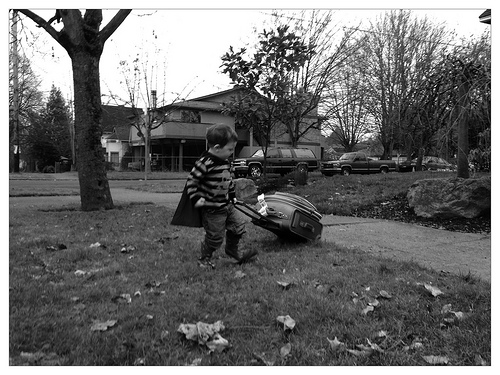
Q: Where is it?
A: This is at the yard.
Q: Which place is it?
A: It is a yard.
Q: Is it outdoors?
A: Yes, it is outdoors.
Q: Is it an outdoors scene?
A: Yes, it is outdoors.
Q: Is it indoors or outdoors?
A: It is outdoors.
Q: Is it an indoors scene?
A: No, it is outdoors.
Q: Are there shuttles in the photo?
A: No, there are no shuttles.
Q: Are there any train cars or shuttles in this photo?
A: No, there are no shuttles or train cars.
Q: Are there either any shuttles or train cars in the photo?
A: No, there are no shuttles or train cars.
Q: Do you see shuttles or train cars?
A: No, there are no shuttles or train cars.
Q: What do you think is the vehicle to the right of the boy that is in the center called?
A: The vehicle is a wagon.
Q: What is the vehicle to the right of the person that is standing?
A: The vehicle is a wagon.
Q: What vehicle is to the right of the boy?
A: The vehicle is a wagon.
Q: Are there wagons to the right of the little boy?
A: Yes, there is a wagon to the right of the boy.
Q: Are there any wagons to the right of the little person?
A: Yes, there is a wagon to the right of the boy.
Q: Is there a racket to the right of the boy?
A: No, there is a wagon to the right of the boy.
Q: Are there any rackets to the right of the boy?
A: No, there is a wagon to the right of the boy.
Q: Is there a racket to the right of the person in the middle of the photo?
A: No, there is a wagon to the right of the boy.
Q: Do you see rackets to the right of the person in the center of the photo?
A: No, there is a wagon to the right of the boy.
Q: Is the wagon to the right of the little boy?
A: Yes, the wagon is to the right of the boy.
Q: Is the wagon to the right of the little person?
A: Yes, the wagon is to the right of the boy.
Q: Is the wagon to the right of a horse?
A: No, the wagon is to the right of the boy.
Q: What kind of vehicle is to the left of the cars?
A: The vehicle is a wagon.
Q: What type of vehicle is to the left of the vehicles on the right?
A: The vehicle is a wagon.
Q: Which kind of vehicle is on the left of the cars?
A: The vehicle is a wagon.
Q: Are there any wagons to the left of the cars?
A: Yes, there is a wagon to the left of the cars.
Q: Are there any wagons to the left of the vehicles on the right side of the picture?
A: Yes, there is a wagon to the left of the cars.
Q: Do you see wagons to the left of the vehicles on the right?
A: Yes, there is a wagon to the left of the cars.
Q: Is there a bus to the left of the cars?
A: No, there is a wagon to the left of the cars.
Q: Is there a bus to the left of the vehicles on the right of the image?
A: No, there is a wagon to the left of the cars.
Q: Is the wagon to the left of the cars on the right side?
A: Yes, the wagon is to the left of the cars.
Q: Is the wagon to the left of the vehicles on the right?
A: Yes, the wagon is to the left of the cars.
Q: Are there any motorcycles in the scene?
A: No, there are no motorcycles.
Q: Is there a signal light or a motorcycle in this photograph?
A: No, there are no motorcycles or traffic lights.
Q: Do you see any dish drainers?
A: No, there are no dish drainers.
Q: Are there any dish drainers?
A: No, there are no dish drainers.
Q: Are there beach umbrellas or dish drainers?
A: No, there are no dish drainers or beach umbrellas.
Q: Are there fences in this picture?
A: No, there are no fences.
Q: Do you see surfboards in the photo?
A: No, there are no surfboards.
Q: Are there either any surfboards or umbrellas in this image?
A: No, there are no surfboards or umbrellas.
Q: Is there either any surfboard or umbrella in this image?
A: No, there are no surfboards or umbrellas.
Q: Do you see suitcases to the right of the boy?
A: Yes, there is a suitcase to the right of the boy.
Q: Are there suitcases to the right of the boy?
A: Yes, there is a suitcase to the right of the boy.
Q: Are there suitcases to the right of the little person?
A: Yes, there is a suitcase to the right of the boy.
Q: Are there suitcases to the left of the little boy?
A: No, the suitcase is to the right of the boy.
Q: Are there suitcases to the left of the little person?
A: No, the suitcase is to the right of the boy.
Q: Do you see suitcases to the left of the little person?
A: No, the suitcase is to the right of the boy.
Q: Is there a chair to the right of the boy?
A: No, there is a suitcase to the right of the boy.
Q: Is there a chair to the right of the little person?
A: No, there is a suitcase to the right of the boy.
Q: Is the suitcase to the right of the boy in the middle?
A: Yes, the suitcase is to the right of the boy.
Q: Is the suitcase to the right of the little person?
A: Yes, the suitcase is to the right of the boy.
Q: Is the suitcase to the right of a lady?
A: No, the suitcase is to the right of the boy.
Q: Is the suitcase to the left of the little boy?
A: No, the suitcase is to the right of the boy.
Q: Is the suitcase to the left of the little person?
A: No, the suitcase is to the right of the boy.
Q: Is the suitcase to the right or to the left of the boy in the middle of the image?
A: The suitcase is to the right of the boy.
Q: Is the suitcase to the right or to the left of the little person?
A: The suitcase is to the right of the boy.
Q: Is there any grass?
A: Yes, there is grass.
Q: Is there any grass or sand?
A: Yes, there is grass.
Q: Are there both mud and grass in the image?
A: No, there is grass but no mud.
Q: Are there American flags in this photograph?
A: No, there are no American flags.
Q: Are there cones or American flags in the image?
A: No, there are no American flags or cones.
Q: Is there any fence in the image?
A: No, there are no fences.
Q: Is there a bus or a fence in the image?
A: No, there are no fences or buses.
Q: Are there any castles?
A: No, there are no castles.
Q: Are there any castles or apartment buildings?
A: No, there are no castles or apartment buildings.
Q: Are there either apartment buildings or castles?
A: No, there are no castles or apartment buildings.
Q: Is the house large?
A: Yes, the house is large.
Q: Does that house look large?
A: Yes, the house is large.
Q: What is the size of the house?
A: The house is large.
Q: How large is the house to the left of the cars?
A: The house is large.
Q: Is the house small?
A: No, the house is large.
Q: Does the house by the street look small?
A: No, the house is large.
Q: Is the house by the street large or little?
A: The house is large.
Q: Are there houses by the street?
A: Yes, there is a house by the street.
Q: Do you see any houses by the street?
A: Yes, there is a house by the street.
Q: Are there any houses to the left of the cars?
A: Yes, there is a house to the left of the cars.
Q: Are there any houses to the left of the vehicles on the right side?
A: Yes, there is a house to the left of the cars.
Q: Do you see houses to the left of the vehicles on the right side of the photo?
A: Yes, there is a house to the left of the cars.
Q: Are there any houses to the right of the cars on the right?
A: No, the house is to the left of the cars.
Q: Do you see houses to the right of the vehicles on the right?
A: No, the house is to the left of the cars.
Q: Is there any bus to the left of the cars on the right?
A: No, there is a house to the left of the cars.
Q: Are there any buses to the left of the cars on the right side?
A: No, there is a house to the left of the cars.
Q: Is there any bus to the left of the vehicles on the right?
A: No, there is a house to the left of the cars.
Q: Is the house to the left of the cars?
A: Yes, the house is to the left of the cars.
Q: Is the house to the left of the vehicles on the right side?
A: Yes, the house is to the left of the cars.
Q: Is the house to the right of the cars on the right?
A: No, the house is to the left of the cars.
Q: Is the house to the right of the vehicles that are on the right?
A: No, the house is to the left of the cars.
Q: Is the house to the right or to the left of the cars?
A: The house is to the left of the cars.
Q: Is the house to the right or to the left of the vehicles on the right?
A: The house is to the left of the cars.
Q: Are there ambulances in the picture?
A: No, there are no ambulances.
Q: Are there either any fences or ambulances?
A: No, there are no ambulances or fences.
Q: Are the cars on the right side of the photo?
A: Yes, the cars are on the right of the image.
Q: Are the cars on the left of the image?
A: No, the cars are on the right of the image.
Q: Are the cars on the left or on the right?
A: The cars are on the right of the image.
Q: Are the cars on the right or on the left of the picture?
A: The cars are on the right of the image.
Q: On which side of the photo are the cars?
A: The cars are on the right of the image.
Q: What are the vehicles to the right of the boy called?
A: The vehicles are cars.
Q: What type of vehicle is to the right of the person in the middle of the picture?
A: The vehicles are cars.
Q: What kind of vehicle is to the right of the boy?
A: The vehicles are cars.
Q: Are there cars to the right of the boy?
A: Yes, there are cars to the right of the boy.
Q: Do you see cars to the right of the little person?
A: Yes, there are cars to the right of the boy.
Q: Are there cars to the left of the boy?
A: No, the cars are to the right of the boy.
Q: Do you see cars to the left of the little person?
A: No, the cars are to the right of the boy.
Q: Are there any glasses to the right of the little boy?
A: No, there are cars to the right of the boy.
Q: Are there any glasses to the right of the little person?
A: No, there are cars to the right of the boy.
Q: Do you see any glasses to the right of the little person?
A: No, there are cars to the right of the boy.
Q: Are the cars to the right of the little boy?
A: Yes, the cars are to the right of the boy.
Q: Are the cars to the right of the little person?
A: Yes, the cars are to the right of the boy.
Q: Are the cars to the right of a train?
A: No, the cars are to the right of the boy.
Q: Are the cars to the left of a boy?
A: No, the cars are to the right of a boy.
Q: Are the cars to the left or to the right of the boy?
A: The cars are to the right of the boy.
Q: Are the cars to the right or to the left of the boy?
A: The cars are to the right of the boy.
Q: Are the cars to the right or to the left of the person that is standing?
A: The cars are to the right of the boy.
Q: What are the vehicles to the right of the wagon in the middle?
A: The vehicles are cars.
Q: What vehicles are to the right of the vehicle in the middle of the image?
A: The vehicles are cars.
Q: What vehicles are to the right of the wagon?
A: The vehicles are cars.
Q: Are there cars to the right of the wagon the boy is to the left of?
A: Yes, there are cars to the right of the wagon.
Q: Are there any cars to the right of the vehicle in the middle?
A: Yes, there are cars to the right of the wagon.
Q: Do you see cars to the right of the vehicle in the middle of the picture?
A: Yes, there are cars to the right of the wagon.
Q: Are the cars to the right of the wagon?
A: Yes, the cars are to the right of the wagon.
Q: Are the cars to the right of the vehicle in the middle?
A: Yes, the cars are to the right of the wagon.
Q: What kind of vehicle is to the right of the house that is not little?
A: The vehicles are cars.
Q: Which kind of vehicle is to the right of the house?
A: The vehicles are cars.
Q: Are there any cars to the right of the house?
A: Yes, there are cars to the right of the house.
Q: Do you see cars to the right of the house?
A: Yes, there are cars to the right of the house.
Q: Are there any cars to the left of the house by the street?
A: No, the cars are to the right of the house.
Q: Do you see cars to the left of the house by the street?
A: No, the cars are to the right of the house.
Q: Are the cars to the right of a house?
A: Yes, the cars are to the right of a house.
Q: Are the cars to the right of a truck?
A: No, the cars are to the right of a house.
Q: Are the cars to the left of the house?
A: No, the cars are to the right of the house.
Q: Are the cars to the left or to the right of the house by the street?
A: The cars are to the right of the house.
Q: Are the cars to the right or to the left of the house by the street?
A: The cars are to the right of the house.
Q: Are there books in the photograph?
A: No, there are no books.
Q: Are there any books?
A: No, there are no books.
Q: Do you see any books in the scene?
A: No, there are no books.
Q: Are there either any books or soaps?
A: No, there are no books or soaps.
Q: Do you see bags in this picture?
A: Yes, there is a bag.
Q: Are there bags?
A: Yes, there is a bag.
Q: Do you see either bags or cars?
A: Yes, there is a bag.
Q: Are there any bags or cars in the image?
A: Yes, there is a bag.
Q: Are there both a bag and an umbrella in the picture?
A: No, there is a bag but no umbrellas.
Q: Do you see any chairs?
A: No, there are no chairs.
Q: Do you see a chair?
A: No, there are no chairs.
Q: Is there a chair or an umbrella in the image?
A: No, there are no chairs or umbrellas.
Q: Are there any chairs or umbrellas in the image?
A: No, there are no chairs or umbrellas.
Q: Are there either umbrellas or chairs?
A: No, there are no chairs or umbrellas.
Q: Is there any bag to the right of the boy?
A: Yes, there is a bag to the right of the boy.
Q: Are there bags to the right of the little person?
A: Yes, there is a bag to the right of the boy.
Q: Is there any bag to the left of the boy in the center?
A: No, the bag is to the right of the boy.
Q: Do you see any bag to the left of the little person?
A: No, the bag is to the right of the boy.